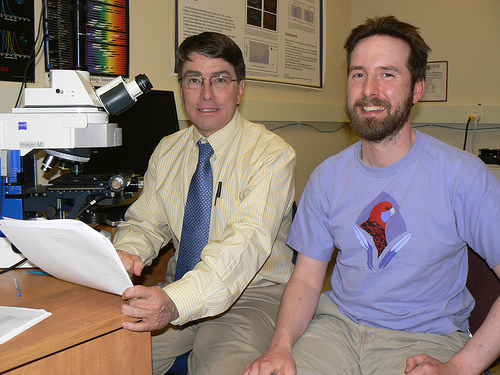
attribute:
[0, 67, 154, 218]
microscope — white, scientific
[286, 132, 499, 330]
tee shirt — purple, light blue, blue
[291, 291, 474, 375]
pants — khaki, tan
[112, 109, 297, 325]
dress shirt — yellow, long sleeved, button up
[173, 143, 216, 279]
tie — long, blue, shiny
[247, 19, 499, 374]
man — smiling, sitting, aged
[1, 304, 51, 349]
papers — stack 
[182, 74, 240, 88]
glasses — present, metal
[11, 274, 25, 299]
pen — blue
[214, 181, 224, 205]
pen — black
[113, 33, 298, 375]
man — older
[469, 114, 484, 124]
outlet — electric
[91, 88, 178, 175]
monitor — computer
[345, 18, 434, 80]
hair — brown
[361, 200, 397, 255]
bird — black, red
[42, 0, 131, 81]
poster — hanging